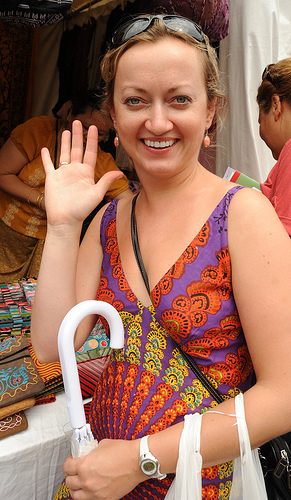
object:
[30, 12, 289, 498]
woman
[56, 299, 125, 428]
handle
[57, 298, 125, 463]
umbrella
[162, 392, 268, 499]
plastic bag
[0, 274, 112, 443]
fabric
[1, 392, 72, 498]
table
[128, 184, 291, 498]
purse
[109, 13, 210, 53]
sunglasses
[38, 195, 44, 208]
ring bracelet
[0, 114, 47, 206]
woman's arm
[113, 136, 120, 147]
earring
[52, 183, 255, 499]
dress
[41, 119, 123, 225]
hand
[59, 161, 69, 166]
ring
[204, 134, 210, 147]
earrings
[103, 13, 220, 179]
head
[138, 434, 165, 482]
watch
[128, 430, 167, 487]
wrist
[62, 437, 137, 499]
hand